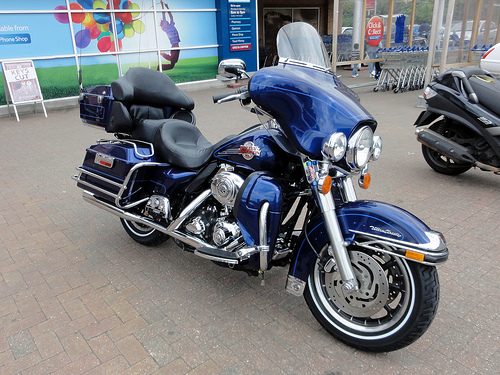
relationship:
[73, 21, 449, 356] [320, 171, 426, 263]
motorcycle has reflectors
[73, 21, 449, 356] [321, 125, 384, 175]
motorcycle has headlights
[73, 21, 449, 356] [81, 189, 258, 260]
motorcycle has tailpipe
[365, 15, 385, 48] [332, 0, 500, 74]
sticker on window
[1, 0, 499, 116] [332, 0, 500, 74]
store has window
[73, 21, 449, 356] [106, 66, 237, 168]
motorcycle has seat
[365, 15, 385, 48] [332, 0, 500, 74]
sticker in window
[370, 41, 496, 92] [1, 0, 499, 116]
carts in front of store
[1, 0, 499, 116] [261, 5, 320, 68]
store has doors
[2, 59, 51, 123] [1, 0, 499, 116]
sign outside store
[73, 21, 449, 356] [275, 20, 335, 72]
motorcycle has windshield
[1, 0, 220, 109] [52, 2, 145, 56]
picture has balloons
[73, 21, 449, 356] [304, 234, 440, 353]
motorcycle has tire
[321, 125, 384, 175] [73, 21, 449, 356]
headlights are on motorcycle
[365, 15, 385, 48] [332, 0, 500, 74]
sticker on a window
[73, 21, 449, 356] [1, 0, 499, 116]
motorcycle in front of store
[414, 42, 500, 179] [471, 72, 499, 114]
motorcycle has seat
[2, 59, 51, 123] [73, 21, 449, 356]
sign in front of motorcycle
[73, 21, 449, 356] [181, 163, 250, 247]
motorcycle has engine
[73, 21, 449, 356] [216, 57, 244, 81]
motorcycle has mirror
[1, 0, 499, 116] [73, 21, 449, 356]
store behind motorcycle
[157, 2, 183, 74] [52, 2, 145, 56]
woman with balloons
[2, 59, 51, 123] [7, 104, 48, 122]
sign has legs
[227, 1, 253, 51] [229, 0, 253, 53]
sign has list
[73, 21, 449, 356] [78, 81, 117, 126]
motorcycle has back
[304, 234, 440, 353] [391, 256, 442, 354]
tire has edge